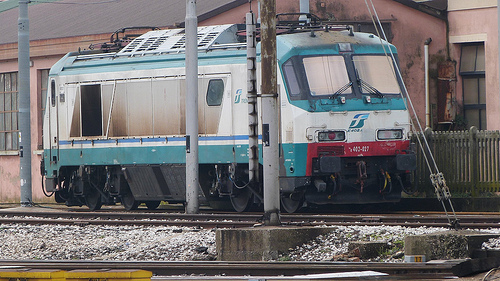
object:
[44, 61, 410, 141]
stripe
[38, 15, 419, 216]
train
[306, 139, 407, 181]
stripe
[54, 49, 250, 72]
stripe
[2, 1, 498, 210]
building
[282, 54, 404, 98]
windshield wipers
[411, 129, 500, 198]
fence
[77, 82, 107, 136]
window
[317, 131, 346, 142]
lights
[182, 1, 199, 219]
poles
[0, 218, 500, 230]
train tracks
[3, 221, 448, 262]
gravel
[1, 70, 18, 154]
window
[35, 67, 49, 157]
window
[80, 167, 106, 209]
wheels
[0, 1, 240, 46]
roof